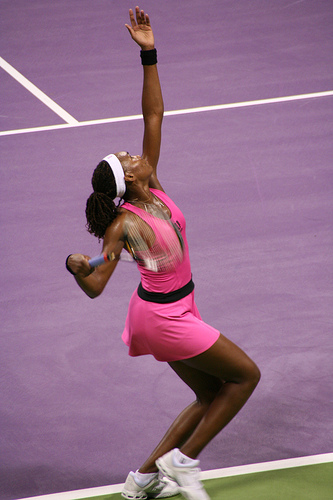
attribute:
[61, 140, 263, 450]
woman — playing, serving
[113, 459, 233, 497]
tennis shoes — white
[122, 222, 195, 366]
dress — black, pink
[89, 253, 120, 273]
handle — blue, red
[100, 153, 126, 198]
headband — white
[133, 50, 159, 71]
wrist band — black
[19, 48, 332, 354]
court — white, purple, green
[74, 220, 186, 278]
racket — moving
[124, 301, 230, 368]
skirt — pink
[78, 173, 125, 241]
hair — black, braided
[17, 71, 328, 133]
stripes — white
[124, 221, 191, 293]
shirt — pink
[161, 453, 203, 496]
shoe — white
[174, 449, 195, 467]
sock — white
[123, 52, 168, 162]
arm — straight out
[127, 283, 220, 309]
belt — black